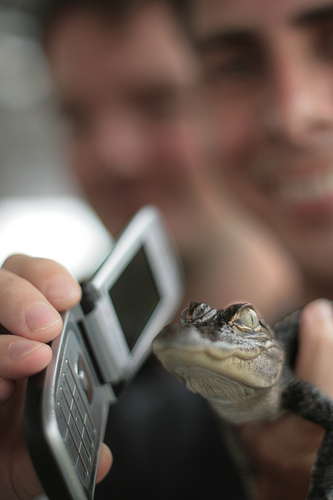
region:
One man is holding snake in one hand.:
[157, 210, 326, 484]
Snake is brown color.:
[184, 303, 315, 422]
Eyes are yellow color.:
[179, 300, 265, 332]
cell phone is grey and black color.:
[21, 227, 166, 482]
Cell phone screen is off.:
[100, 252, 166, 338]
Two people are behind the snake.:
[47, 51, 326, 288]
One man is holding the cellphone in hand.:
[13, 257, 145, 492]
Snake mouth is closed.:
[139, 314, 277, 410]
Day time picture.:
[17, 62, 314, 473]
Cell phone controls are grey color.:
[57, 354, 99, 478]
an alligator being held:
[140, 251, 329, 458]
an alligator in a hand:
[150, 258, 331, 444]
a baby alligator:
[140, 243, 330, 430]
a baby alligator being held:
[166, 254, 332, 464]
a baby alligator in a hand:
[148, 251, 323, 458]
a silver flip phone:
[28, 195, 194, 499]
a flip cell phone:
[36, 205, 188, 498]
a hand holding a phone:
[11, 212, 182, 492]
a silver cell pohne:
[30, 197, 202, 495]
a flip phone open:
[31, 197, 189, 497]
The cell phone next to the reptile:
[18, 196, 191, 499]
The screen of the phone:
[104, 242, 162, 356]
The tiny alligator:
[150, 295, 331, 499]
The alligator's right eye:
[176, 299, 210, 324]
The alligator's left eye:
[220, 302, 265, 333]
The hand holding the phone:
[0, 251, 113, 497]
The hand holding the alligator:
[229, 299, 331, 497]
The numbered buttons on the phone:
[58, 357, 97, 483]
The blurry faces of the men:
[32, 1, 331, 286]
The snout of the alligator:
[147, 319, 283, 390]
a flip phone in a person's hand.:
[22, 205, 187, 498]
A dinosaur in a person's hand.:
[140, 293, 332, 497]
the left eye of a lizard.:
[227, 303, 274, 339]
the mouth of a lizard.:
[147, 332, 266, 368]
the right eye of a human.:
[188, 21, 274, 110]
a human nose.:
[248, 76, 328, 142]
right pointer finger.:
[46, 247, 103, 315]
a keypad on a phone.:
[34, 345, 126, 490]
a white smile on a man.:
[240, 170, 330, 203]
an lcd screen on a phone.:
[105, 243, 169, 363]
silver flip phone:
[26, 209, 202, 498]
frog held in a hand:
[145, 273, 330, 455]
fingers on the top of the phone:
[2, 247, 95, 381]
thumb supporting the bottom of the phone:
[81, 431, 120, 486]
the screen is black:
[105, 245, 176, 356]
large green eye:
[235, 297, 264, 334]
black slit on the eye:
[247, 312, 254, 326]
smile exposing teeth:
[251, 162, 331, 217]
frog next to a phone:
[15, 238, 319, 491]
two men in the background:
[44, 7, 331, 249]